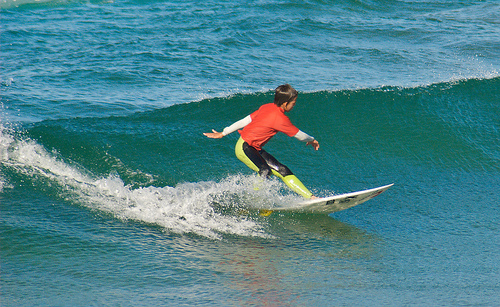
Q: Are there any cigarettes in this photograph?
A: No, there are no cigarettes.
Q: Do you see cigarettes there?
A: No, there are no cigarettes.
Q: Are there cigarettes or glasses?
A: No, there are no cigarettes or glasses.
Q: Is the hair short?
A: Yes, the hair is short.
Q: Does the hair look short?
A: Yes, the hair is short.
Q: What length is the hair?
A: The hair is short.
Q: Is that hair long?
A: No, the hair is short.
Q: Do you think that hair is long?
A: No, the hair is short.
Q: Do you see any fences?
A: No, there are no fences.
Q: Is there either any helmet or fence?
A: No, there are no fences or helmets.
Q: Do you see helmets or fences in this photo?
A: No, there are no fences or helmets.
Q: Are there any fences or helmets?
A: No, there are no fences or helmets.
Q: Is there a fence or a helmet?
A: No, there are no fences or helmets.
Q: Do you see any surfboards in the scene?
A: Yes, there is a surfboard.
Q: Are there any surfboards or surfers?
A: Yes, there is a surfboard.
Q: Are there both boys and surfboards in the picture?
A: Yes, there are both a surfboard and a boy.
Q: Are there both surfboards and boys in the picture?
A: Yes, there are both a surfboard and a boy.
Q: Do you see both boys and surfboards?
A: Yes, there are both a surfboard and a boy.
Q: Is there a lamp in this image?
A: No, there are no lamps.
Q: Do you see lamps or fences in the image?
A: No, there are no lamps or fences.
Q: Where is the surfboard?
A: The surfboard is on the water.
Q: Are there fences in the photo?
A: No, there are no fences.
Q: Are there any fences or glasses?
A: No, there are no fences or glasses.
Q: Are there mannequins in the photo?
A: No, there are no mannequins.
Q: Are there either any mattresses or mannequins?
A: No, there are no mannequins or mattresses.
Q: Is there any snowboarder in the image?
A: No, there are no snowboarders.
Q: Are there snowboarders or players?
A: No, there are no snowboarders or players.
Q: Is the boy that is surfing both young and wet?
A: Yes, the boy is young and wet.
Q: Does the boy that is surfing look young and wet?
A: Yes, the boy is young and wet.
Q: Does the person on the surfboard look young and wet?
A: Yes, the boy is young and wet.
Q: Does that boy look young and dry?
A: No, the boy is young but wet.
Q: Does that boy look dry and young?
A: No, the boy is young but wet.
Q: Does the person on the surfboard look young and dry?
A: No, the boy is young but wet.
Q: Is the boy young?
A: Yes, the boy is young.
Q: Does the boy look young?
A: Yes, the boy is young.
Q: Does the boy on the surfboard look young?
A: Yes, the boy is young.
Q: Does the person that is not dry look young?
A: Yes, the boy is young.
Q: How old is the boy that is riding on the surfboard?
A: The boy is young.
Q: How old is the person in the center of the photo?
A: The boy is young.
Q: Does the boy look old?
A: No, the boy is young.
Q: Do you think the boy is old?
A: No, the boy is young.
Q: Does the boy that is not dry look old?
A: No, the boy is young.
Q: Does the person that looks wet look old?
A: No, the boy is young.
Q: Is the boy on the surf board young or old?
A: The boy is young.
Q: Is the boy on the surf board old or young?
A: The boy is young.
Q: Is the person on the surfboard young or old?
A: The boy is young.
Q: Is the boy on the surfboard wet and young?
A: Yes, the boy is wet and young.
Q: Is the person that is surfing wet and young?
A: Yes, the boy is wet and young.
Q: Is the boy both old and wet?
A: No, the boy is wet but young.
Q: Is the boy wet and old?
A: No, the boy is wet but young.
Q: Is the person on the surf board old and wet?
A: No, the boy is wet but young.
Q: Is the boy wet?
A: Yes, the boy is wet.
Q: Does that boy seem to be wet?
A: Yes, the boy is wet.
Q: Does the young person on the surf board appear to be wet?
A: Yes, the boy is wet.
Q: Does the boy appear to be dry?
A: No, the boy is wet.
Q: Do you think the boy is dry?
A: No, the boy is wet.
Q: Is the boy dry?
A: No, the boy is wet.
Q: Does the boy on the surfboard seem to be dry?
A: No, the boy is wet.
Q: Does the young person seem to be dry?
A: No, the boy is wet.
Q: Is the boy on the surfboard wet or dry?
A: The boy is wet.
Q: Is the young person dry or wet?
A: The boy is wet.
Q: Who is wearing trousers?
A: The boy is wearing trousers.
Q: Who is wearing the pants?
A: The boy is wearing trousers.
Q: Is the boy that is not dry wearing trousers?
A: Yes, the boy is wearing trousers.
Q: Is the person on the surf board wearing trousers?
A: Yes, the boy is wearing trousers.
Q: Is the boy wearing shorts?
A: No, the boy is wearing trousers.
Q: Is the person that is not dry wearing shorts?
A: No, the boy is wearing trousers.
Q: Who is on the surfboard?
A: The boy is on the surfboard.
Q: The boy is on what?
A: The boy is on the surfboard.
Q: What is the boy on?
A: The boy is on the surfboard.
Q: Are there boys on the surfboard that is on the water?
A: Yes, there is a boy on the surfboard.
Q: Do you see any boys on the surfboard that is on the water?
A: Yes, there is a boy on the surfboard.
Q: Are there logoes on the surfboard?
A: No, there is a boy on the surfboard.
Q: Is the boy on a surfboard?
A: Yes, the boy is on a surfboard.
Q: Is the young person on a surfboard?
A: Yes, the boy is on a surfboard.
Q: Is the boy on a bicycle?
A: No, the boy is on a surfboard.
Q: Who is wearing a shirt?
A: The boy is wearing a shirt.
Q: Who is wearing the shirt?
A: The boy is wearing a shirt.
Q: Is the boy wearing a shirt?
A: Yes, the boy is wearing a shirt.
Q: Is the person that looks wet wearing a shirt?
A: Yes, the boy is wearing a shirt.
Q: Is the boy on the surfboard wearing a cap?
A: No, the boy is wearing a shirt.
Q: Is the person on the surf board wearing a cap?
A: No, the boy is wearing a shirt.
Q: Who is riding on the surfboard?
A: The boy is riding on the surfboard.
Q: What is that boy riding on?
A: The boy is riding on the surfboard.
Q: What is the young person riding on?
A: The boy is riding on the surfboard.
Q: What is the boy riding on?
A: The boy is riding on the surfboard.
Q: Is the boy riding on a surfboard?
A: Yes, the boy is riding on a surfboard.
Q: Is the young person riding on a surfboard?
A: Yes, the boy is riding on a surfboard.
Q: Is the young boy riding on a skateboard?
A: No, the boy is riding on a surfboard.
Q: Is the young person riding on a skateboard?
A: No, the boy is riding on a surfboard.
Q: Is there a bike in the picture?
A: No, there are no bikes.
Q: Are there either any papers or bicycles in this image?
A: No, there are no bicycles or papers.